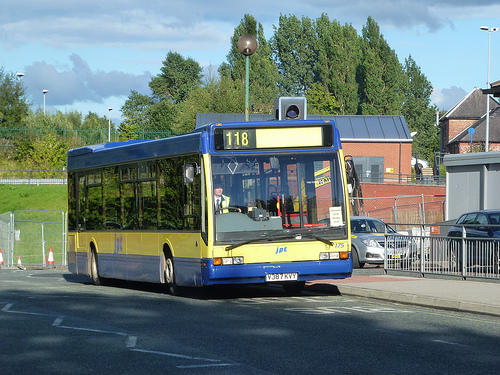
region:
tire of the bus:
[163, 253, 176, 293]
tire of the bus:
[87, 243, 104, 282]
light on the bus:
[232, 253, 247, 268]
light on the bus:
[219, 253, 234, 268]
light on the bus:
[211, 255, 223, 268]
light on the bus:
[316, 250, 330, 262]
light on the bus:
[326, 250, 340, 262]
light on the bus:
[337, 248, 349, 262]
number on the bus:
[239, 130, 251, 147]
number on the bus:
[230, 128, 242, 146]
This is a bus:
[55, 118, 362, 305]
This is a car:
[348, 212, 427, 280]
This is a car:
[446, 203, 499, 269]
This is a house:
[337, 105, 424, 185]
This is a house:
[442, 77, 492, 152]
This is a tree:
[405, 49, 457, 164]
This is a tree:
[380, 26, 425, 122]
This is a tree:
[358, 32, 390, 120]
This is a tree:
[322, 11, 366, 119]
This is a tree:
[272, 13, 315, 95]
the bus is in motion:
[27, 105, 410, 307]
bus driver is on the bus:
[174, 159, 264, 241]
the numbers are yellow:
[195, 108, 272, 178]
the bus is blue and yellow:
[0, 83, 384, 301]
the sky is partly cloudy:
[15, 3, 460, 103]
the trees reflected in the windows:
[40, 154, 205, 239]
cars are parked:
[320, 186, 495, 276]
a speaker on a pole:
[227, 14, 271, 115]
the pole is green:
[226, 57, 263, 118]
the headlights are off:
[182, 240, 360, 276]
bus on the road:
[65, 132, 362, 281]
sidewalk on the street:
[363, 270, 499, 312]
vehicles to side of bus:
[355, 203, 499, 273]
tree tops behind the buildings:
[170, 8, 440, 115]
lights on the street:
[11, 65, 120, 112]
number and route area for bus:
[212, 119, 332, 151]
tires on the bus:
[76, 240, 182, 289]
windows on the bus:
[73, 163, 194, 230]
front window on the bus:
[213, 162, 340, 232]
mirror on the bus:
[173, 163, 203, 188]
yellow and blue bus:
[61, 111, 359, 299]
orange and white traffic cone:
[33, 235, 67, 279]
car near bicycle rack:
[351, 208, 466, 287]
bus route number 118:
[64, 114, 361, 297]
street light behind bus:
[212, 23, 297, 303]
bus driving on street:
[51, 114, 498, 349]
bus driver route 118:
[176, 127, 286, 251]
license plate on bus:
[218, 244, 333, 302]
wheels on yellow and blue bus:
[63, 231, 212, 296]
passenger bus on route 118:
[58, 110, 376, 293]